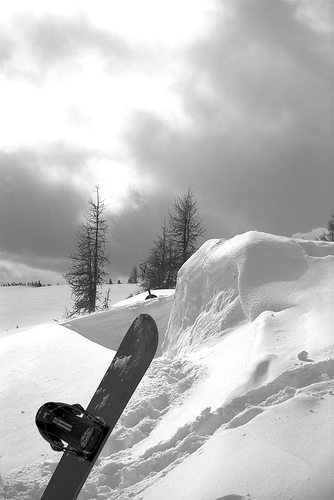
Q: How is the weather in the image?
A: It is cloudy.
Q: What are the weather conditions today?
A: It is cloudy.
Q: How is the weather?
A: It is cloudy.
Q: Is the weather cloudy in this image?
A: Yes, it is cloudy.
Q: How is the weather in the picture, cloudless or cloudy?
A: It is cloudy.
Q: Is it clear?
A: No, it is cloudy.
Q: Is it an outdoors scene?
A: Yes, it is outdoors.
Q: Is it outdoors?
A: Yes, it is outdoors.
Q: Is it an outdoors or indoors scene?
A: It is outdoors.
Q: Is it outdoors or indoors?
A: It is outdoors.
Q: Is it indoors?
A: No, it is outdoors.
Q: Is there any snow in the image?
A: Yes, there is snow.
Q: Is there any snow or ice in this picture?
A: Yes, there is snow.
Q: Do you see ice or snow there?
A: Yes, there is snow.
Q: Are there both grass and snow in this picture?
A: No, there is snow but no grass.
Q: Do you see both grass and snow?
A: No, there is snow but no grass.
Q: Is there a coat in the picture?
A: No, there are no coats.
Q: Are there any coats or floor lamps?
A: No, there are no coats or floor lamps.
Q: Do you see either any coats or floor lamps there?
A: No, there are no coats or floor lamps.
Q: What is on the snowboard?
A: The snow is on the snowboard.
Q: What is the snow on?
A: The snow is on the snowboard.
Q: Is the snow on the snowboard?
A: Yes, the snow is on the snowboard.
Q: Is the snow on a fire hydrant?
A: No, the snow is on the snowboard.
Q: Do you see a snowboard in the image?
A: Yes, there is a snowboard.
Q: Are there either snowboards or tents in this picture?
A: Yes, there is a snowboard.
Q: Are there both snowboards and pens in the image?
A: No, there is a snowboard but no pens.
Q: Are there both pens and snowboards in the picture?
A: No, there is a snowboard but no pens.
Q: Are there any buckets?
A: No, there are no buckets.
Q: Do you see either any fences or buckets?
A: No, there are no buckets or fences.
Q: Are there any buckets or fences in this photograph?
A: No, there are no buckets or fences.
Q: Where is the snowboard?
A: The snowboard is in the snow.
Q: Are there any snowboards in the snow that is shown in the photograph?
A: Yes, there is a snowboard in the snow.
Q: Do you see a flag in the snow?
A: No, there is a snowboard in the snow.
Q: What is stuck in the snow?
A: The snowboard is stuck in the snow.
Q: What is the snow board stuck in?
A: The snow board is stuck in the snow.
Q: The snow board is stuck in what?
A: The snow board is stuck in the snow.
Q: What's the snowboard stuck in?
A: The snow board is stuck in the snow.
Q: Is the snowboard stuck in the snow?
A: Yes, the snowboard is stuck in the snow.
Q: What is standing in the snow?
A: The snowboard is standing in the snow.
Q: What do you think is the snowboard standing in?
A: The snowboard is standing in the snow.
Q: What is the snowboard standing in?
A: The snowboard is standing in the snow.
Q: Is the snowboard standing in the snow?
A: Yes, the snowboard is standing in the snow.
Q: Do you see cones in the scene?
A: No, there are no cones.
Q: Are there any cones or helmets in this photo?
A: No, there are no cones or helmets.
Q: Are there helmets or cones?
A: No, there are no cones or helmets.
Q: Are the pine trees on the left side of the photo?
A: Yes, the pine trees are on the left of the image.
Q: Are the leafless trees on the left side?
A: Yes, the pine trees are on the left of the image.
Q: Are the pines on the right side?
A: No, the pines are on the left of the image.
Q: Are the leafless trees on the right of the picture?
A: No, the pines are on the left of the image.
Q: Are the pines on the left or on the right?
A: The pines are on the left of the image.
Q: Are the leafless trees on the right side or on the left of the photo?
A: The pines are on the left of the image.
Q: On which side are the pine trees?
A: The pine trees are on the left of the image.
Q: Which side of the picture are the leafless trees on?
A: The pine trees are on the left of the image.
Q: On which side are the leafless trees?
A: The pine trees are on the left of the image.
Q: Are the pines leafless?
A: Yes, the pines are leafless.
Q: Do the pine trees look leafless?
A: Yes, the pine trees are leafless.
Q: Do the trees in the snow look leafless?
A: Yes, the pine trees are leafless.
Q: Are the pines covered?
A: No, the pines are leafless.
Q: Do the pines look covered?
A: No, the pines are leafless.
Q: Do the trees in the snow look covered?
A: No, the pines are leafless.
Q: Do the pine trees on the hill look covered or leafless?
A: The pines are leafless.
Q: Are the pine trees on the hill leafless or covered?
A: The pines are leafless.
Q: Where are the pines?
A: The pines are in the snow.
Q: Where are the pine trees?
A: The pines are in the snow.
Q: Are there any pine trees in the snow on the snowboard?
A: Yes, there are pine trees in the snow.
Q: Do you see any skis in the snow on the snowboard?
A: No, there are pine trees in the snow.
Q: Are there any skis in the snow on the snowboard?
A: No, there are pine trees in the snow.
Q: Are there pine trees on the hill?
A: Yes, there are pine trees on the hill.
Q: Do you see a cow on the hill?
A: No, there are pine trees on the hill.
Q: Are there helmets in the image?
A: No, there are no helmets.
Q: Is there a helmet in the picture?
A: No, there are no helmets.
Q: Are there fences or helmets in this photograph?
A: No, there are no helmets or fences.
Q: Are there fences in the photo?
A: No, there are no fences.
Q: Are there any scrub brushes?
A: No, there are no scrub brushes.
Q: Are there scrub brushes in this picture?
A: No, there are no scrub brushes.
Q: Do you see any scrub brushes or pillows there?
A: No, there are no scrub brushes or pillows.